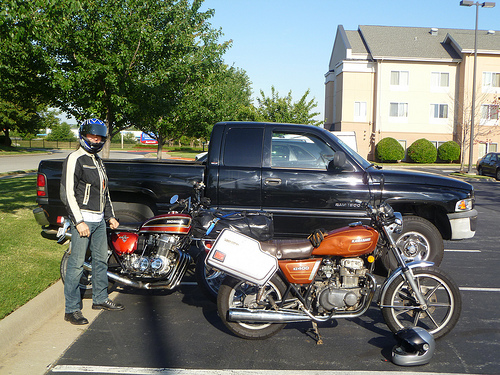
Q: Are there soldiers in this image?
A: No, there are no soldiers.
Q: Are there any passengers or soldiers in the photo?
A: No, there are no soldiers or passengers.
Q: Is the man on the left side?
A: Yes, the man is on the left of the image.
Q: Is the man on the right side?
A: No, the man is on the left of the image.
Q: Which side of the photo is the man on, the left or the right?
A: The man is on the left of the image.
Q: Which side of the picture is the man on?
A: The man is on the left of the image.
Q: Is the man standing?
A: Yes, the man is standing.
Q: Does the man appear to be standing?
A: Yes, the man is standing.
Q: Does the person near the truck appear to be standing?
A: Yes, the man is standing.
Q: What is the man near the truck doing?
A: The man is standing.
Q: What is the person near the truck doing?
A: The man is standing.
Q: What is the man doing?
A: The man is standing.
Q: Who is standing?
A: The man is standing.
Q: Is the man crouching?
A: No, the man is standing.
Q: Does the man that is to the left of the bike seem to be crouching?
A: No, the man is standing.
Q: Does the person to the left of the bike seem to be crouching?
A: No, the man is standing.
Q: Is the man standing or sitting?
A: The man is standing.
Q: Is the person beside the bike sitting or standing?
A: The man is standing.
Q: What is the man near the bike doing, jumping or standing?
A: The man is standing.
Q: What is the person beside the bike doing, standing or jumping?
A: The man is standing.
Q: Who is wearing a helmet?
A: The man is wearing a helmet.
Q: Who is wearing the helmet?
A: The man is wearing a helmet.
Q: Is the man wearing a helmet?
A: Yes, the man is wearing a helmet.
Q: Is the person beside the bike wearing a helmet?
A: Yes, the man is wearing a helmet.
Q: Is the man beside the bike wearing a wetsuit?
A: No, the man is wearing a helmet.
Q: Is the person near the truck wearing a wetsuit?
A: No, the man is wearing a helmet.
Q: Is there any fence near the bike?
A: No, there is a man near the bike.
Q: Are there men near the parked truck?
A: Yes, there is a man near the truck.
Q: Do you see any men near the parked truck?
A: Yes, there is a man near the truck.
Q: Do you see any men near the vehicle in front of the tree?
A: Yes, there is a man near the truck.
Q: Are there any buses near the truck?
A: No, there is a man near the truck.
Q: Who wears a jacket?
A: The man wears a jacket.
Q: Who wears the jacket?
A: The man wears a jacket.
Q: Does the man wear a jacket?
A: Yes, the man wears a jacket.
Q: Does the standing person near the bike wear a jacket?
A: Yes, the man wears a jacket.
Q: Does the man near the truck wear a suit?
A: No, the man wears a jacket.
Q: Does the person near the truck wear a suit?
A: No, the man wears a jacket.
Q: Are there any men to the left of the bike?
A: Yes, there is a man to the left of the bike.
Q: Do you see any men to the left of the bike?
A: Yes, there is a man to the left of the bike.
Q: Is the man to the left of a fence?
A: No, the man is to the left of the bike.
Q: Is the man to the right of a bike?
A: No, the man is to the left of a bike.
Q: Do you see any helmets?
A: Yes, there is a helmet.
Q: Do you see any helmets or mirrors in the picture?
A: Yes, there is a helmet.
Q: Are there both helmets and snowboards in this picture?
A: No, there is a helmet but no snowboards.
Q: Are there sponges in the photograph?
A: No, there are no sponges.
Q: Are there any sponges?
A: No, there are no sponges.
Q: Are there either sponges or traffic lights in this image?
A: No, there are no sponges or traffic lights.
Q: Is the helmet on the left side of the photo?
A: Yes, the helmet is on the left of the image.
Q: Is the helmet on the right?
A: No, the helmet is on the left of the image.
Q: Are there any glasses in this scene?
A: No, there are no glasses.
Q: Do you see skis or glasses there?
A: No, there are no glasses or skis.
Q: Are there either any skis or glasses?
A: No, there are no glasses or skis.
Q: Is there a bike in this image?
A: Yes, there is a bike.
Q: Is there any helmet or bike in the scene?
A: Yes, there is a bike.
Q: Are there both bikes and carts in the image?
A: No, there is a bike but no carts.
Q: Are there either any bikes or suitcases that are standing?
A: Yes, the bike is standing.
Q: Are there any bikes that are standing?
A: Yes, there is a bike that is standing.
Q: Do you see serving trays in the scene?
A: No, there are no serving trays.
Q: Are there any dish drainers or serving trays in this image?
A: No, there are no serving trays or dish drainers.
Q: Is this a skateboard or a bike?
A: This is a bike.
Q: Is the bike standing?
A: Yes, the bike is standing.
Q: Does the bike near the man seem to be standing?
A: Yes, the bike is standing.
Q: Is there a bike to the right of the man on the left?
A: Yes, there is a bike to the right of the man.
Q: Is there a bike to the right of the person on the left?
A: Yes, there is a bike to the right of the man.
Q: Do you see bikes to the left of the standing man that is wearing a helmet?
A: No, the bike is to the right of the man.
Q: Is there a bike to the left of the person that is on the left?
A: No, the bike is to the right of the man.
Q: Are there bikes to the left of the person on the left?
A: No, the bike is to the right of the man.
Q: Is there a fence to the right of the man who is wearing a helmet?
A: No, there is a bike to the right of the man.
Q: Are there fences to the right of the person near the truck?
A: No, there is a bike to the right of the man.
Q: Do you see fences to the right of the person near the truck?
A: No, there is a bike to the right of the man.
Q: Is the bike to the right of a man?
A: Yes, the bike is to the right of a man.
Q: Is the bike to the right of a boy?
A: No, the bike is to the right of a man.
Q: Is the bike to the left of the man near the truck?
A: No, the bike is to the right of the man.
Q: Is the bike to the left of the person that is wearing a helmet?
A: No, the bike is to the right of the man.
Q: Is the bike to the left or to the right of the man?
A: The bike is to the right of the man.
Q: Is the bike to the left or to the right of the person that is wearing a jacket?
A: The bike is to the right of the man.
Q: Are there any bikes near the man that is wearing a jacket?
A: Yes, there is a bike near the man.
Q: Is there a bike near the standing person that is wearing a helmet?
A: Yes, there is a bike near the man.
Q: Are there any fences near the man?
A: No, there is a bike near the man.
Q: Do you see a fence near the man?
A: No, there is a bike near the man.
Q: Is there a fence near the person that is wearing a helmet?
A: No, there is a bike near the man.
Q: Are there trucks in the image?
A: Yes, there is a truck.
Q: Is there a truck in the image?
A: Yes, there is a truck.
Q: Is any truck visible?
A: Yes, there is a truck.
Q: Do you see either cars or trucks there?
A: Yes, there is a truck.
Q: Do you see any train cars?
A: No, there are no train cars.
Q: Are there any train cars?
A: No, there are no train cars.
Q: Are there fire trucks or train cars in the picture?
A: No, there are no train cars or fire trucks.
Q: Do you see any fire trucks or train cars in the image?
A: No, there are no train cars or fire trucks.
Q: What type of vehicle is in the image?
A: The vehicle is a truck.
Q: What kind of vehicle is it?
A: The vehicle is a truck.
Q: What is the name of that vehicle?
A: That is a truck.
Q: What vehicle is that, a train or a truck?
A: That is a truck.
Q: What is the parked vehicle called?
A: The vehicle is a truck.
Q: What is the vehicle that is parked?
A: The vehicle is a truck.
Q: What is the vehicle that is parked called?
A: The vehicle is a truck.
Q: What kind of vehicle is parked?
A: The vehicle is a truck.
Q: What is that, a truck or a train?
A: That is a truck.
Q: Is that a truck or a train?
A: That is a truck.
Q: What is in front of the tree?
A: The truck is in front of the tree.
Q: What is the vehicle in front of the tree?
A: The vehicle is a truck.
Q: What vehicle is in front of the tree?
A: The vehicle is a truck.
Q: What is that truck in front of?
A: The truck is in front of the tree.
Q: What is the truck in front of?
A: The truck is in front of the tree.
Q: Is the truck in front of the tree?
A: Yes, the truck is in front of the tree.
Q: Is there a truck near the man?
A: Yes, there is a truck near the man.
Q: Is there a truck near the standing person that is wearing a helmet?
A: Yes, there is a truck near the man.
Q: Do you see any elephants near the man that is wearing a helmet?
A: No, there is a truck near the man.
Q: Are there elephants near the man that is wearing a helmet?
A: No, there is a truck near the man.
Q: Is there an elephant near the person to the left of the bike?
A: No, there is a truck near the man.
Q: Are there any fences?
A: No, there are no fences.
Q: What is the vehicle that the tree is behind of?
A: The vehicle is a truck.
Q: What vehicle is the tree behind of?
A: The tree is behind the truck.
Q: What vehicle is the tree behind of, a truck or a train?
A: The tree is behind a truck.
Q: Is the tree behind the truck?
A: Yes, the tree is behind the truck.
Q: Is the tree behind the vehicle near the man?
A: Yes, the tree is behind the truck.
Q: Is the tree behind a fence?
A: No, the tree is behind the truck.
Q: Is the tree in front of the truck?
A: No, the tree is behind the truck.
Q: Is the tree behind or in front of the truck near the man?
A: The tree is behind the truck.